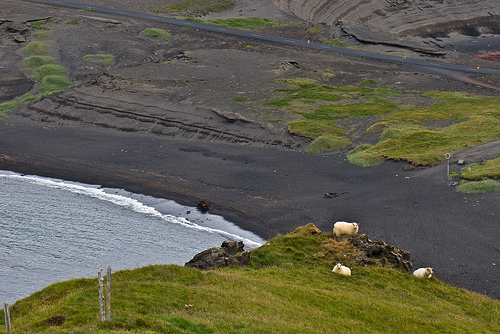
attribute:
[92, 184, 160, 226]
waves — small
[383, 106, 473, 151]
grass — small, growing, patchy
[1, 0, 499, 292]
sandy seashore — large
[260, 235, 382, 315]
landscape — part, green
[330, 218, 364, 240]
sheep — white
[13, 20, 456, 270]
beach — dark, sandy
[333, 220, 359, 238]
sheep — white, grazing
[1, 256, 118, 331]
trunks — old, standing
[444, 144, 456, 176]
sign — red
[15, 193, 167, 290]
water — body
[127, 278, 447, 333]
landscape — part, green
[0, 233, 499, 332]
green landscape — part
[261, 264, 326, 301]
landscape — green, part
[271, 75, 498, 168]
grass — patchy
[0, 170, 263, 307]
water — calm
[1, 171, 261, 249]
waves — small, breaking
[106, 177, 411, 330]
landscape — green, part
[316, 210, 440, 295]
sheeps — three, white, wooly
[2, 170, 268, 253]
wave — breaking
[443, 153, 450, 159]
signboard — red, white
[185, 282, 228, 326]
green landscape — part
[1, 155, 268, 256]
shore — covered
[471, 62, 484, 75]
sign — orange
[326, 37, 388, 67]
roadway — painted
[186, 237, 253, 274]
outcrop — rocky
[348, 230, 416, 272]
outcrop — rocky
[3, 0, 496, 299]
sand — black